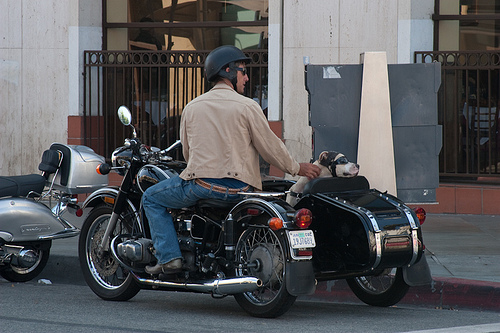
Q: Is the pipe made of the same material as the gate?
A: Yes, both the pipe and the gate are made of metal.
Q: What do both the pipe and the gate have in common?
A: The material, both the pipe and the gate are metallic.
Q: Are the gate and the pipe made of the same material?
A: Yes, both the gate and the pipe are made of metal.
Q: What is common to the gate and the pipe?
A: The material, both the gate and the pipe are metallic.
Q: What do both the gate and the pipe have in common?
A: The material, both the gate and the pipe are metallic.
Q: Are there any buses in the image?
A: No, there are no buses.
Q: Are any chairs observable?
A: No, there are no chairs.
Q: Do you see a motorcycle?
A: Yes, there is a motorcycle.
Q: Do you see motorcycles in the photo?
A: Yes, there is a motorcycle.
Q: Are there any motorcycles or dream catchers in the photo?
A: Yes, there is a motorcycle.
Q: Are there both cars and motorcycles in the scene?
A: Yes, there are both a motorcycle and a car.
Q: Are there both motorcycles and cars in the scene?
A: Yes, there are both a motorcycle and a car.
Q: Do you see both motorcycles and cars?
A: Yes, there are both a motorcycle and a car.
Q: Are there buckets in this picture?
A: No, there are no buckets.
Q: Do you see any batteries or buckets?
A: No, there are no buckets or batteries.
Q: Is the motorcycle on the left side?
A: Yes, the motorcycle is on the left of the image.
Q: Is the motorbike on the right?
A: No, the motorbike is on the left of the image.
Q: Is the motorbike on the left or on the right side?
A: The motorbike is on the left of the image.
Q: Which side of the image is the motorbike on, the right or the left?
A: The motorbike is on the left of the image.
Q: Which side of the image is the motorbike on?
A: The motorbike is on the left of the image.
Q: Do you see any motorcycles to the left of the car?
A: Yes, there is a motorcycle to the left of the car.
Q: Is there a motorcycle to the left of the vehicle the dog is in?
A: Yes, there is a motorcycle to the left of the car.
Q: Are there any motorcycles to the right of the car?
A: No, the motorcycle is to the left of the car.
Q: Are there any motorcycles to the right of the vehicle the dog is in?
A: No, the motorcycle is to the left of the car.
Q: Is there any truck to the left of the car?
A: No, there is a motorcycle to the left of the car.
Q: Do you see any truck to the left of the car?
A: No, there is a motorcycle to the left of the car.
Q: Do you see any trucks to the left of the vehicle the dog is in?
A: No, there is a motorcycle to the left of the car.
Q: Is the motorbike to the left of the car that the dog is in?
A: Yes, the motorbike is to the left of the car.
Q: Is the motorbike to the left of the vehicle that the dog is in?
A: Yes, the motorbike is to the left of the car.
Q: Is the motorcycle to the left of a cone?
A: No, the motorcycle is to the left of the car.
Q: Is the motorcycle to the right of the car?
A: No, the motorcycle is to the left of the car.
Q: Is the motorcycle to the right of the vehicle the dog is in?
A: No, the motorcycle is to the left of the car.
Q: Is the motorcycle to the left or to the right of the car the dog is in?
A: The motorcycle is to the left of the car.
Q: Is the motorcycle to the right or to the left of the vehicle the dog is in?
A: The motorcycle is to the left of the car.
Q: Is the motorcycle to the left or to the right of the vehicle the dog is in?
A: The motorcycle is to the left of the car.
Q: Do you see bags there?
A: No, there are no bags.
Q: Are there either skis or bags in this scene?
A: No, there are no bags or skis.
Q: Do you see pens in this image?
A: No, there are no pens.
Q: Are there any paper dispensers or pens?
A: No, there are no pens or paper dispensers.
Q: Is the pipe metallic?
A: Yes, the pipe is metallic.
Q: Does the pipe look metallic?
A: Yes, the pipe is metallic.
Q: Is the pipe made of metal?
A: Yes, the pipe is made of metal.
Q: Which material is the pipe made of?
A: The pipe is made of metal.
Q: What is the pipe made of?
A: The pipe is made of metal.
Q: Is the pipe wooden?
A: No, the pipe is metallic.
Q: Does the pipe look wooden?
A: No, the pipe is metallic.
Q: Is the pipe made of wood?
A: No, the pipe is made of metal.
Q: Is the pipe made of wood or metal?
A: The pipe is made of metal.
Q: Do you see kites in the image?
A: No, there are no kites.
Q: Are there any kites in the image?
A: No, there are no kites.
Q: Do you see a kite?
A: No, there are no kites.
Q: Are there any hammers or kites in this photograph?
A: No, there are no kites or hammers.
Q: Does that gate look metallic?
A: Yes, the gate is metallic.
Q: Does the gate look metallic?
A: Yes, the gate is metallic.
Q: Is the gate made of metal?
A: Yes, the gate is made of metal.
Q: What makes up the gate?
A: The gate is made of metal.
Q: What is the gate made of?
A: The gate is made of metal.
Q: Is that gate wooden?
A: No, the gate is metallic.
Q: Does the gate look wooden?
A: No, the gate is metallic.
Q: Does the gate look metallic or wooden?
A: The gate is metallic.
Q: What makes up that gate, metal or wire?
A: The gate is made of metal.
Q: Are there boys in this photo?
A: No, there are no boys.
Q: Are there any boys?
A: No, there are no boys.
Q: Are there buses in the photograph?
A: No, there are no buses.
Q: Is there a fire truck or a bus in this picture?
A: No, there are no buses or fire trucks.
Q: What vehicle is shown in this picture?
A: The vehicle is a car.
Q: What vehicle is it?
A: The vehicle is a car.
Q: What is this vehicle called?
A: This is a car.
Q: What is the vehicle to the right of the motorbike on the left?
A: The vehicle is a car.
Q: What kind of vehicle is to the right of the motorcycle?
A: The vehicle is a car.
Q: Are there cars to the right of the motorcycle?
A: Yes, there is a car to the right of the motorcycle.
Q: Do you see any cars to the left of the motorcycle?
A: No, the car is to the right of the motorcycle.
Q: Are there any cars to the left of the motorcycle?
A: No, the car is to the right of the motorcycle.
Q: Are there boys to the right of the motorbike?
A: No, there is a car to the right of the motorbike.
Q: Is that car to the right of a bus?
A: No, the car is to the right of the motorcycle.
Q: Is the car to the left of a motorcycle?
A: No, the car is to the right of a motorcycle.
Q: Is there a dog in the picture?
A: Yes, there is a dog.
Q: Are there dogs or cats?
A: Yes, there is a dog.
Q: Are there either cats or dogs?
A: Yes, there is a dog.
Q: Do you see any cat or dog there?
A: Yes, there is a dog.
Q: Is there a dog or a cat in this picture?
A: Yes, there is a dog.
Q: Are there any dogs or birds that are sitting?
A: Yes, the dog is sitting.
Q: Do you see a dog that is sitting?
A: Yes, there is a dog that is sitting.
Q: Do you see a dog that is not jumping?
A: Yes, there is a dog that is sitting .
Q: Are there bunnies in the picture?
A: No, there are no bunnies.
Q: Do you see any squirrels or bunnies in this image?
A: No, there are no bunnies or squirrels.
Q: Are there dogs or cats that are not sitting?
A: No, there is a dog but it is sitting.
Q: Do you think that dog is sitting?
A: Yes, the dog is sitting.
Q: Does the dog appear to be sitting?
A: Yes, the dog is sitting.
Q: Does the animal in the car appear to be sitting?
A: Yes, the dog is sitting.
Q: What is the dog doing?
A: The dog is sitting.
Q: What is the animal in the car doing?
A: The dog is sitting.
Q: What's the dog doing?
A: The dog is sitting.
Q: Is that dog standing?
A: No, the dog is sitting.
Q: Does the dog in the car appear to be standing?
A: No, the dog is sitting.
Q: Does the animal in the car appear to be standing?
A: No, the dog is sitting.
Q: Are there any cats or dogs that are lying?
A: No, there is a dog but it is sitting.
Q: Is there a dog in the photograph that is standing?
A: No, there is a dog but it is sitting.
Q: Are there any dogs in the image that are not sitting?
A: No, there is a dog but it is sitting.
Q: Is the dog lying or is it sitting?
A: The dog is sitting.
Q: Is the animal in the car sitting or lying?
A: The dog is sitting.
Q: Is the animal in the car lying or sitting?
A: The dog is sitting.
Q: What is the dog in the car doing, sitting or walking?
A: The dog is sitting.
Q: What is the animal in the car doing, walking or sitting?
A: The dog is sitting.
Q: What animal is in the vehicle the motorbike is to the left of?
A: The dog is in the car.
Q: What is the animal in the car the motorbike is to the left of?
A: The animal is a dog.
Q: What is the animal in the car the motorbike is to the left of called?
A: The animal is a dog.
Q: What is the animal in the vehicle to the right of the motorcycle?
A: The animal is a dog.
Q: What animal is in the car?
A: The animal is a dog.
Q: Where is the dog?
A: The dog is in the car.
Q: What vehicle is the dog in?
A: The dog is in the car.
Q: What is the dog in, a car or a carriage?
A: The dog is in a car.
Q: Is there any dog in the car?
A: Yes, there is a dog in the car.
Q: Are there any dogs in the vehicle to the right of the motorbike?
A: Yes, there is a dog in the car.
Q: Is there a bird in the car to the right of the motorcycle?
A: No, there is a dog in the car.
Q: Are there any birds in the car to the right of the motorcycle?
A: No, there is a dog in the car.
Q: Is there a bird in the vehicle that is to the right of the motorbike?
A: No, there is a dog in the car.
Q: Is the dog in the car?
A: Yes, the dog is in the car.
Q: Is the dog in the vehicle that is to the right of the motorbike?
A: Yes, the dog is in the car.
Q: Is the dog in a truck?
A: No, the dog is in the car.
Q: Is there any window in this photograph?
A: Yes, there is a window.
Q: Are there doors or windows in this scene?
A: Yes, there is a window.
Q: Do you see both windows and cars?
A: Yes, there are both a window and a car.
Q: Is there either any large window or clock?
A: Yes, there is a large window.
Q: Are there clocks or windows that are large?
A: Yes, the window is large.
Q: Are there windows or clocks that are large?
A: Yes, the window is large.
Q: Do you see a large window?
A: Yes, there is a large window.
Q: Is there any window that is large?
A: Yes, there is a window that is large.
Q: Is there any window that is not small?
A: Yes, there is a large window.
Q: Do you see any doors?
A: No, there are no doors.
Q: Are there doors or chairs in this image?
A: No, there are no doors or chairs.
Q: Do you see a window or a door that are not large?
A: No, there is a window but it is large.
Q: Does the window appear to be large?
A: Yes, the window is large.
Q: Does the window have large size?
A: Yes, the window is large.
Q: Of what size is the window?
A: The window is large.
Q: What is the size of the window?
A: The window is large.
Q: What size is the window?
A: The window is large.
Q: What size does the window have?
A: The window has large size.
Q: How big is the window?
A: The window is large.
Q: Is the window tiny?
A: No, the window is large.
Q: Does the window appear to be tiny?
A: No, the window is large.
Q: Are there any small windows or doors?
A: No, there is a window but it is large.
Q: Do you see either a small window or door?
A: No, there is a window but it is large.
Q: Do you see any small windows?
A: No, there is a window but it is large.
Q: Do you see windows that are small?
A: No, there is a window but it is large.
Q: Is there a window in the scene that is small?
A: No, there is a window but it is large.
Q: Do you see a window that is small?
A: No, there is a window but it is large.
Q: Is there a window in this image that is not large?
A: No, there is a window but it is large.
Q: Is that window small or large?
A: The window is large.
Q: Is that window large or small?
A: The window is large.